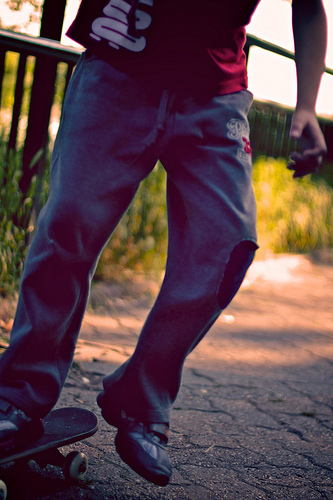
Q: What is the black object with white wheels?
A: A skateboard.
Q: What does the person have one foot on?
A: A skateboard.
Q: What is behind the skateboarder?
A: A wooden fence.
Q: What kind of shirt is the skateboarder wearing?
A: A red t-shirt.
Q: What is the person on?
A: A skateboard.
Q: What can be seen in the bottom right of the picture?
A: Part of a skateboard.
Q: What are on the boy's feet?
A: Black shoes.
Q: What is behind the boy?
A: Tall grass.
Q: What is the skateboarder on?
A: A portion of the driveway.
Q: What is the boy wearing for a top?
A: A red shirt.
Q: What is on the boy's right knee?
A: A patch.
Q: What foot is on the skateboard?
A: The boy's right foot.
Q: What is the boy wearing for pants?
A: He is wearing sweatpants.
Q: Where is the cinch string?
A: Pants.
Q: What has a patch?
A: Knee of pants.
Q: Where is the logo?
A: Left side of pants.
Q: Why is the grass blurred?
A: Out of focus.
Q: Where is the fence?
A: Behind the man.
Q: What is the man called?
A: Skateboarder.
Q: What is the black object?
A: Skateboard.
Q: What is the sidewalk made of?
A: Cobblestones.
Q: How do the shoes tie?
A: Velcro.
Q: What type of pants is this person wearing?
A: Sweat pants.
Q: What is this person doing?
A: Skateboarding.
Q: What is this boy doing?
A: Skateboarding.